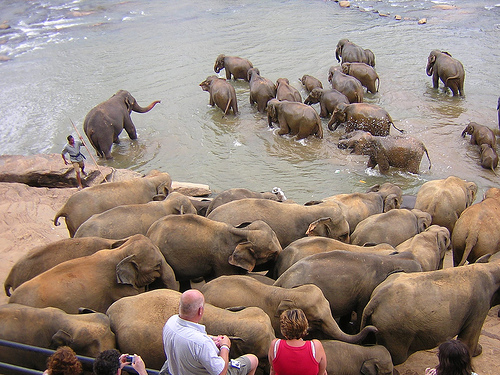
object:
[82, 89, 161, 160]
elephant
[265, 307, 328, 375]
woman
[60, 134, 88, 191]
man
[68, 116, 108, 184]
stick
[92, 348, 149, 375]
person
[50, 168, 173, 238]
elephants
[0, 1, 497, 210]
water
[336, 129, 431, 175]
elephant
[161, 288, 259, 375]
man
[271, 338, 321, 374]
tank top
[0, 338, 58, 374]
guard rail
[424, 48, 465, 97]
elephant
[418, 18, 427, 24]
rock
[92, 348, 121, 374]
black hair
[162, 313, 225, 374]
shirt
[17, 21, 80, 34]
wave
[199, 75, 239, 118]
elephant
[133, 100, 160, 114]
trunk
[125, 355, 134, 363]
camera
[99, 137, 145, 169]
shadow